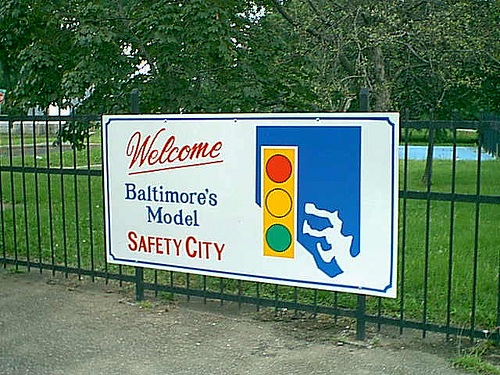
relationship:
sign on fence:
[86, 78, 405, 283] [19, 55, 470, 329]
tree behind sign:
[136, 20, 364, 103] [86, 78, 405, 283]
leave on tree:
[142, 57, 215, 94] [136, 20, 364, 103]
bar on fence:
[53, 99, 109, 315] [19, 55, 470, 329]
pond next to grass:
[380, 130, 486, 170] [87, 202, 99, 227]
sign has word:
[86, 78, 405, 283] [108, 127, 264, 285]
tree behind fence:
[136, 20, 364, 103] [19, 55, 470, 329]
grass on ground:
[87, 202, 99, 227] [35, 224, 106, 290]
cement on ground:
[28, 291, 96, 317] [35, 224, 106, 290]